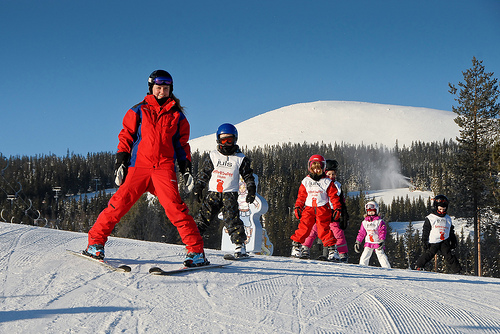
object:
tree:
[388, 196, 398, 226]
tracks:
[360, 288, 402, 331]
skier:
[87, 67, 211, 269]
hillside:
[186, 100, 498, 150]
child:
[194, 123, 256, 259]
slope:
[2, 219, 500, 333]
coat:
[355, 214, 387, 247]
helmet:
[216, 121, 238, 146]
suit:
[76, 93, 211, 268]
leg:
[147, 179, 204, 252]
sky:
[1, 1, 500, 162]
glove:
[113, 153, 130, 183]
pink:
[304, 221, 349, 254]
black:
[197, 148, 257, 201]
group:
[85, 70, 465, 275]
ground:
[0, 220, 500, 333]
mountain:
[177, 98, 500, 165]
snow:
[0, 100, 500, 333]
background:
[0, 2, 499, 278]